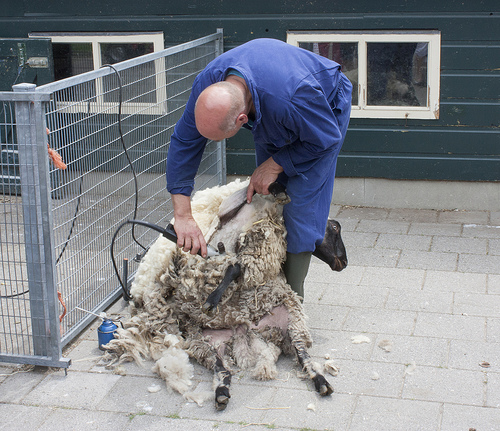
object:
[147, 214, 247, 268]
sized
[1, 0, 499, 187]
wall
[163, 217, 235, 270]
buzzers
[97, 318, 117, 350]
can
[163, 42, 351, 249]
coat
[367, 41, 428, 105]
window glass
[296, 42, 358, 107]
window glass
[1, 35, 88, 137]
gate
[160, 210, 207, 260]
hand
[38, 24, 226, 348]
fence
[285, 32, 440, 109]
window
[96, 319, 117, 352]
oil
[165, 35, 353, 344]
man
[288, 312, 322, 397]
leg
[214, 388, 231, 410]
hooves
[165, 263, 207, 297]
wool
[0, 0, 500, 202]
building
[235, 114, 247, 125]
ear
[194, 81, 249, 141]
bald head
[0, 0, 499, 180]
green building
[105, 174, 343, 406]
sheep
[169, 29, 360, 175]
man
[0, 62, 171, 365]
metal fence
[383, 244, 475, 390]
stones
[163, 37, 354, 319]
shearer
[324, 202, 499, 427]
paved area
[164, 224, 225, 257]
hair clipper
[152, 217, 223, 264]
electric shear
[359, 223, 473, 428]
ground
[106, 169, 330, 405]
coat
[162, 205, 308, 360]
shorn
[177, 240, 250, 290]
clippers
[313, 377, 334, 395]
hoof